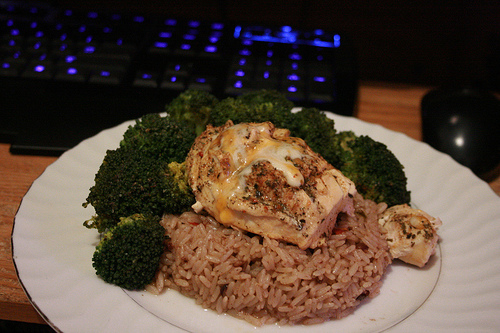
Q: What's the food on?
A: Plate.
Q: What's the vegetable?
A: Broccoli.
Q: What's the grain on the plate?
A: Rice.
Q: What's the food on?
A: Plate.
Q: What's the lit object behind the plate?
A: Keyboard.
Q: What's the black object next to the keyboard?
A: Mouse.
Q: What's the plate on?
A: Desk.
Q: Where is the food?
A: On the plate.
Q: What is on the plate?
A: The food.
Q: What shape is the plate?
A: Round.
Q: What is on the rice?
A: Chicken.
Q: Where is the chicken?
A: On the rice.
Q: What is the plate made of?
A: Glass.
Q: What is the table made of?
A: Wood.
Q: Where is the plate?
A: On the table.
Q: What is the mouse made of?
A: Plastic.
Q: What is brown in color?
A: The food.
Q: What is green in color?
A: The food.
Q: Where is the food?
A: On the plate.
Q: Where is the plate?
A: Under the food.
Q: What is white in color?
A: The plate.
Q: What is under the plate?
A: The table.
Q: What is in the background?
A: Blue lights.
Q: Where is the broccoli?
A: On the plate.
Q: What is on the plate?
A: A stuffed chicken breast.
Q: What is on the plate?
A: Pile of rice.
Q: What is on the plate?
A: Broccoli.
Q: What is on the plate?
A: Food.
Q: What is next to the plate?
A: A computer mouse.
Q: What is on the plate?
A: A chicken dinner.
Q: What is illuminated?
A: A keyboard.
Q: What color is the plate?
A: White.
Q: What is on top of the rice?
A: Chicken.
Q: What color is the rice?
A: Brown.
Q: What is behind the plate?
A: Keyboard and mouse.